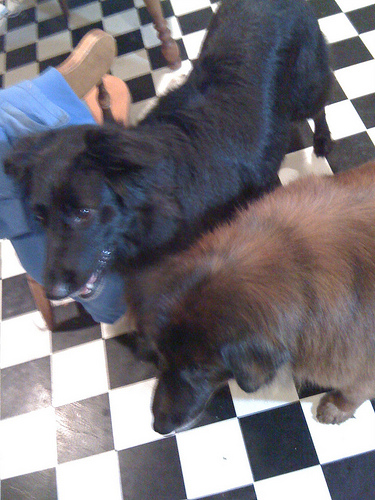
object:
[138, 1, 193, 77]
leg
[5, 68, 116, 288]
clothing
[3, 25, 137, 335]
chair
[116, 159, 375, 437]
dogs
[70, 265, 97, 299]
mouth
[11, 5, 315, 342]
dog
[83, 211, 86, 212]
light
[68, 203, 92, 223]
eye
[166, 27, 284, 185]
coat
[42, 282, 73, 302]
nose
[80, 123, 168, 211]
ear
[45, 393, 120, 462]
tile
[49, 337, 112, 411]
tile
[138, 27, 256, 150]
fur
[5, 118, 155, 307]
head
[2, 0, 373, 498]
floor